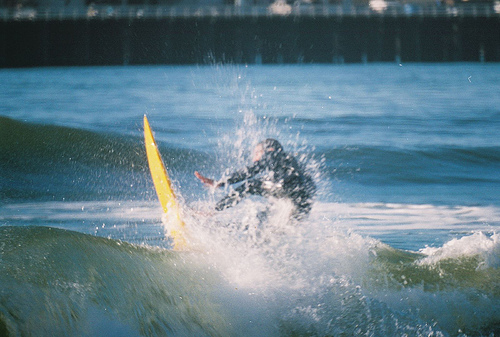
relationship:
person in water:
[191, 131, 321, 244] [0, 60, 500, 335]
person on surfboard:
[191, 134, 320, 251] [140, 114, 203, 257]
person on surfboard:
[191, 134, 320, 251] [138, 109, 212, 258]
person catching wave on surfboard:
[191, 134, 320, 251] [139, 112, 198, 250]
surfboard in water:
[143, 112, 191, 242] [2, 61, 498, 335]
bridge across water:
[0, 2, 498, 63] [2, 61, 498, 335]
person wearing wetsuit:
[191, 134, 320, 251] [212, 143, 321, 217]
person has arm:
[191, 134, 320, 251] [221, 150, 276, 190]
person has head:
[191, 134, 320, 251] [248, 136, 279, 158]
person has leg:
[191, 134, 320, 251] [213, 175, 277, 213]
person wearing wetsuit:
[191, 134, 320, 251] [218, 148, 318, 222]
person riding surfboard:
[191, 134, 320, 251] [139, 112, 198, 250]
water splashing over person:
[175, 50, 355, 254] [191, 134, 320, 251]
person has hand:
[191, 134, 320, 251] [190, 168, 216, 186]